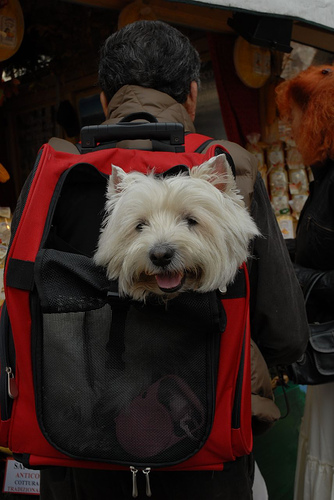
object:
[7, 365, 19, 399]
zipper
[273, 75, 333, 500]
woman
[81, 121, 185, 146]
handle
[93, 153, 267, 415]
dog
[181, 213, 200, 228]
eyes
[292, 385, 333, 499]
skirt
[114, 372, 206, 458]
leash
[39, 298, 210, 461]
pocket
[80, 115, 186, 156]
tv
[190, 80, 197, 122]
ear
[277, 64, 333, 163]
hair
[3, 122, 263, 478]
backpack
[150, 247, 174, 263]
nose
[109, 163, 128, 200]
ears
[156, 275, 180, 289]
tougne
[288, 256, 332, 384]
bag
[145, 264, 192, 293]
mouth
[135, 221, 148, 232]
eye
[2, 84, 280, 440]
brown vest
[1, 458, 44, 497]
sign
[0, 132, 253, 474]
back pack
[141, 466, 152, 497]
zipper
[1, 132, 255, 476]
dog/backpack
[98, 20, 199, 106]
head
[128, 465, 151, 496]
zipper handles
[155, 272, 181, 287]
tongue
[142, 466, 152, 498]
zipper pull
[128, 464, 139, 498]
zipper pull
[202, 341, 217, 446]
zipper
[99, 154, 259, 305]
head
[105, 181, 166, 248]
fur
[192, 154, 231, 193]
ear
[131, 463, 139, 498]
zipper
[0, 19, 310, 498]
man